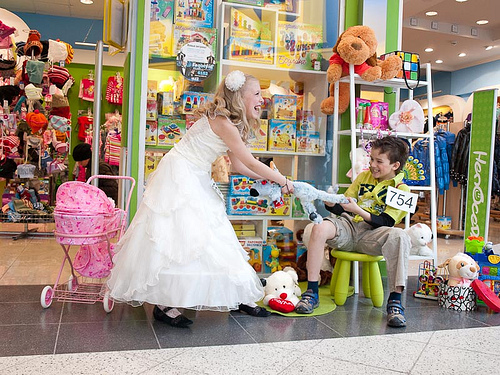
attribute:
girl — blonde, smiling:
[103, 68, 296, 327]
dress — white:
[109, 114, 267, 309]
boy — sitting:
[294, 136, 418, 328]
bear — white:
[261, 262, 302, 314]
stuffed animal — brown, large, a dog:
[318, 25, 399, 115]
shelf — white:
[330, 57, 442, 267]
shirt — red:
[328, 51, 371, 75]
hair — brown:
[369, 134, 409, 175]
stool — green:
[328, 247, 388, 309]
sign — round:
[174, 41, 217, 82]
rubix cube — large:
[379, 49, 421, 81]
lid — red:
[470, 277, 499, 312]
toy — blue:
[251, 161, 350, 226]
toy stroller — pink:
[40, 172, 136, 312]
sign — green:
[463, 87, 496, 245]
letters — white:
[470, 146, 487, 239]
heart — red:
[268, 296, 295, 314]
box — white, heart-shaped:
[386, 98, 425, 135]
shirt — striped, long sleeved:
[103, 132, 123, 165]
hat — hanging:
[46, 39, 69, 64]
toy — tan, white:
[435, 252, 482, 285]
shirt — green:
[340, 168, 413, 224]